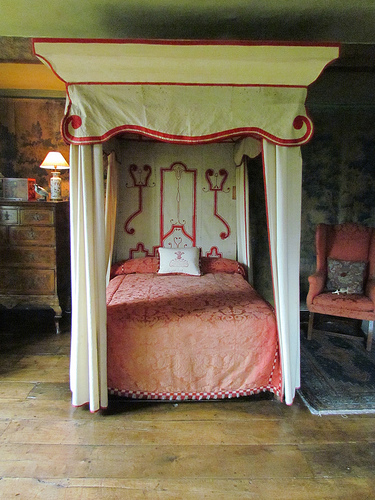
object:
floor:
[0, 313, 373, 498]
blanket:
[107, 256, 286, 403]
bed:
[98, 248, 275, 407]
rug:
[287, 323, 374, 419]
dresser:
[0, 205, 70, 335]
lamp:
[40, 151, 71, 200]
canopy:
[30, 37, 343, 409]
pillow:
[201, 257, 248, 276]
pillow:
[155, 247, 204, 275]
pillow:
[112, 254, 157, 276]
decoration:
[124, 156, 233, 260]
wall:
[0, 38, 369, 327]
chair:
[305, 218, 374, 353]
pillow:
[325, 258, 369, 294]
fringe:
[105, 342, 284, 400]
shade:
[40, 154, 69, 172]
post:
[284, 93, 295, 411]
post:
[233, 141, 252, 276]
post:
[66, 78, 102, 417]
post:
[92, 123, 124, 276]